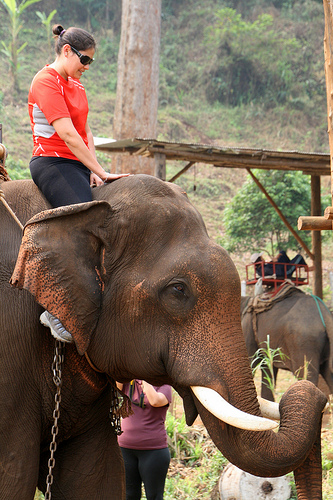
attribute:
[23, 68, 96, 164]
top — red, short sleeved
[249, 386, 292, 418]
tusk — part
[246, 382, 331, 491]
trunk — part, long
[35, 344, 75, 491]
chain — part, metal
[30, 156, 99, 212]
trouser — part, black stretch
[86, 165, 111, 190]
hand — part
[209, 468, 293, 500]
stone — part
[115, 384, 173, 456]
top — part, plain purple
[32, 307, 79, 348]
shoe — part, gray, blue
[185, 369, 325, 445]
tusks — white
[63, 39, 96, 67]
sunglasses — black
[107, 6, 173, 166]
stem — deciduous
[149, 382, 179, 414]
sleeve — part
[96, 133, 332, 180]
platform — wooden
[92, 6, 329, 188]
terrain — hilly